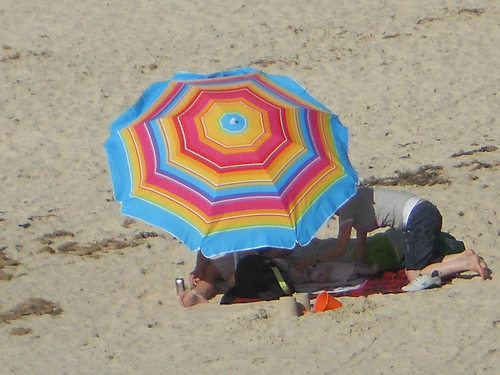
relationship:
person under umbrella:
[293, 171, 493, 281] [105, 66, 358, 256]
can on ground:
[175, 278, 183, 295] [1, 1, 499, 365]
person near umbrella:
[293, 171, 493, 281] [105, 66, 358, 256]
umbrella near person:
[105, 66, 358, 256] [293, 171, 493, 281]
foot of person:
[467, 255, 484, 284] [290, 185, 484, 284]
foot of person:
[459, 248, 484, 265] [290, 185, 484, 284]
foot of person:
[181, 290, 206, 308] [176, 247, 282, 303]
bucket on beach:
[314, 290, 341, 311] [4, 2, 484, 371]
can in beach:
[169, 274, 187, 294] [4, 2, 500, 371]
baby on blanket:
[286, 258, 384, 283] [218, 265, 415, 305]